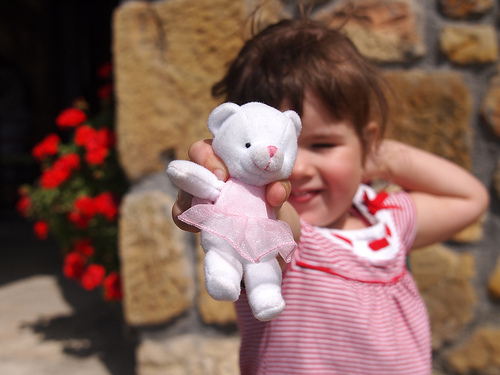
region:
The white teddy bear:
[155, 95, 315, 327]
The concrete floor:
[1, 261, 131, 373]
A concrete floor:
[3, 265, 120, 373]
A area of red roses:
[1, 100, 130, 308]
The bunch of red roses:
[8, 105, 125, 315]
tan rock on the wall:
[311, 0, 436, 64]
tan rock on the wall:
[401, 236, 471, 351]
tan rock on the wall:
[437, 316, 494, 368]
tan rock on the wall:
[130, 330, 245, 370]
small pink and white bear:
[157, 100, 337, 322]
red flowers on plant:
[17, 105, 149, 311]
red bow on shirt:
[360, 187, 407, 219]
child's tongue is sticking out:
[284, 182, 321, 215]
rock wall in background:
[122, 77, 197, 330]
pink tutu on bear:
[177, 191, 299, 262]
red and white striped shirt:
[255, 185, 435, 372]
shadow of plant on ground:
[19, 297, 92, 372]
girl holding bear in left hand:
[148, 91, 310, 313]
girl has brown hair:
[220, 5, 383, 125]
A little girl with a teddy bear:
[107, 17, 472, 355]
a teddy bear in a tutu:
[154, 97, 328, 324]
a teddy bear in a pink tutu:
[137, 78, 313, 335]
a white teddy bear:
[117, 73, 362, 332]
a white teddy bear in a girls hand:
[144, 96, 352, 339]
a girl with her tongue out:
[225, 63, 377, 255]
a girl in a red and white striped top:
[103, 64, 459, 373]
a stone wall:
[103, 46, 218, 368]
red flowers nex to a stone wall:
[23, 69, 182, 365]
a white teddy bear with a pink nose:
[191, 99, 320, 201]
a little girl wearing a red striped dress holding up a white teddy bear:
[147, 18, 489, 370]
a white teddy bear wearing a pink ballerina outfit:
[155, 98, 298, 325]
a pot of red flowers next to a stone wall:
[20, 90, 145, 335]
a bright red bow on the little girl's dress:
[359, 186, 402, 221]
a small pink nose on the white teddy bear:
[265, 143, 277, 155]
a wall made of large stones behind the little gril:
[354, 1, 498, 139]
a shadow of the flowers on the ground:
[17, 310, 110, 372]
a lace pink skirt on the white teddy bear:
[173, 203, 301, 265]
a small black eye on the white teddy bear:
[239, 139, 256, 149]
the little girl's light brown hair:
[246, 34, 387, 112]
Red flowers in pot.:
[38, 131, 129, 321]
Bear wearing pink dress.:
[193, 203, 283, 303]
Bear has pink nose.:
[258, 143, 295, 182]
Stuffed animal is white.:
[179, 128, 307, 352]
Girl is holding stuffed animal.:
[161, 156, 311, 367]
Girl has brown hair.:
[269, 76, 411, 165]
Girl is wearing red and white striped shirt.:
[298, 256, 355, 336]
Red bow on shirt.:
[368, 180, 413, 252]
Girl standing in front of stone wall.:
[165, 77, 466, 373]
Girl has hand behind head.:
[343, 119, 431, 256]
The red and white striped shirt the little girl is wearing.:
[227, 184, 442, 373]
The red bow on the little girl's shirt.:
[362, 189, 397, 211]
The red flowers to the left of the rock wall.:
[23, 94, 135, 322]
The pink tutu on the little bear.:
[187, 200, 289, 256]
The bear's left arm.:
[159, 152, 235, 200]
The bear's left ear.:
[203, 99, 235, 131]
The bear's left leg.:
[196, 226, 240, 294]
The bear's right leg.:
[250, 257, 290, 320]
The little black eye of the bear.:
[243, 135, 251, 156]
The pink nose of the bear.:
[255, 140, 285, 165]